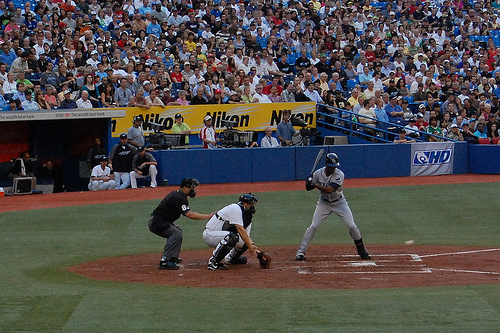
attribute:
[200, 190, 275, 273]
man — playing baseball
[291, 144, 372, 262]
man — playing baseball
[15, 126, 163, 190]
team — baseball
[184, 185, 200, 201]
mask — face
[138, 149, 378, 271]
men — trying to catch ball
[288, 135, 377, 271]
man — ready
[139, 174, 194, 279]
umpire — officiating game, getting ready to make call, waiting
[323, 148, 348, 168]
helmet — batting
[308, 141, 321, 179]
bat — baseball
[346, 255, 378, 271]
plate — home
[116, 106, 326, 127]
sign — yellow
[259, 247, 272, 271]
glove — baseball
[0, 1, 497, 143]
fans — baseball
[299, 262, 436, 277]
lines — white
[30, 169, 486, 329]
field — green